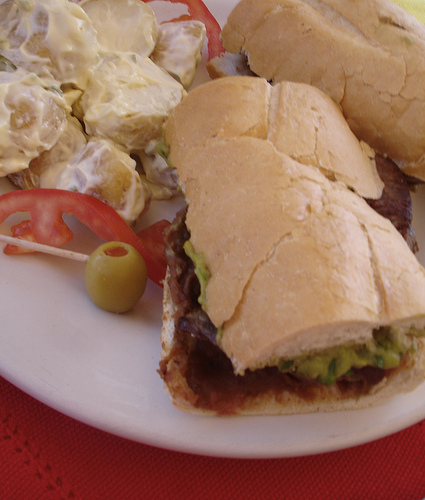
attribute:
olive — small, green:
[84, 239, 149, 311]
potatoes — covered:
[0, 0, 207, 229]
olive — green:
[72, 229, 145, 318]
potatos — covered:
[0, 0, 207, 214]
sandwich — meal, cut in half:
[140, 60, 423, 410]